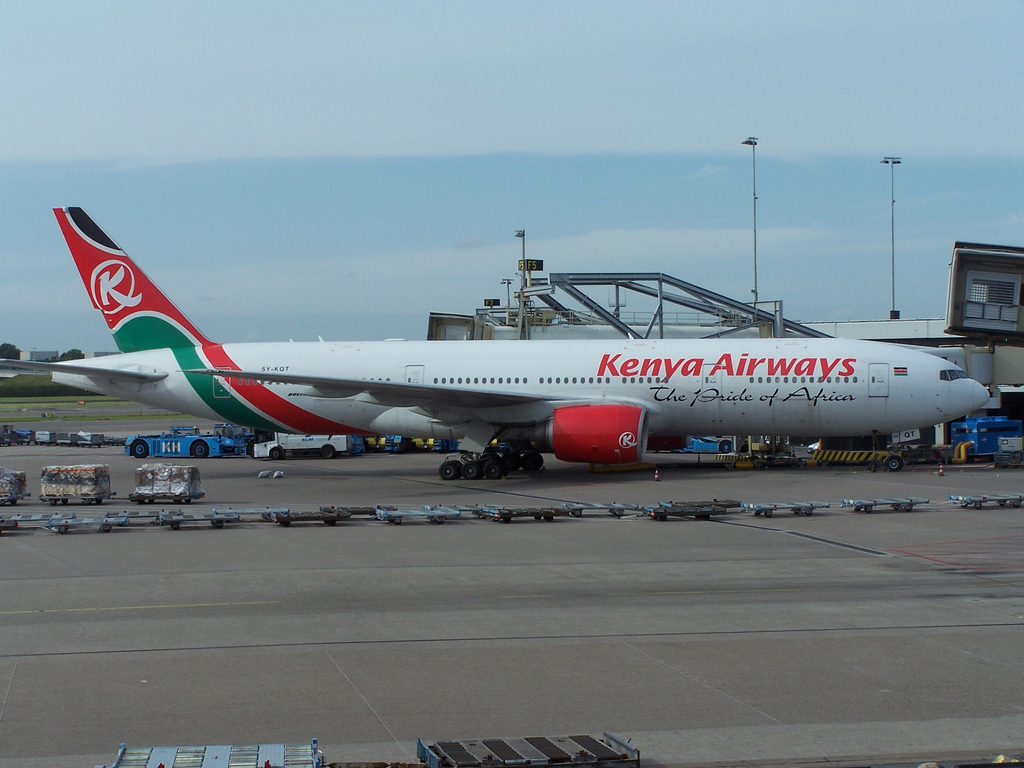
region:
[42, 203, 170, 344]
tail of the plane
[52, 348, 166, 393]
wing on the plane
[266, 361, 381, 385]
wing on the plane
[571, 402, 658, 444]
engine on the plane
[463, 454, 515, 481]
wheel of the plane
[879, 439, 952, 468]
wheel on the plane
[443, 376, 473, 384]
window on the plane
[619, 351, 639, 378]
red letter on plane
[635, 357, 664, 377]
red letter on plane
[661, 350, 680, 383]
red letter on plane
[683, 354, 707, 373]
red letter on plane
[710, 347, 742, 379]
red letter on plane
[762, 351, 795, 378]
red letter on plane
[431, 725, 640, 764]
luggage trailer on tarmac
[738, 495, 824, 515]
luggage trailer on tarmac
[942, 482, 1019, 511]
luggage trailer on tarmac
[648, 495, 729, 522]
luggage trailer on tarmac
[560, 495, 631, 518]
luggage trailer on tarmac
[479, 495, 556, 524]
luggage trailer on tarmac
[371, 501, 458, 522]
luggage trailer on tarmac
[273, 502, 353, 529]
luggage trailer on tarmac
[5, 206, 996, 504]
A jet plane at the airport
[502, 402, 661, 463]
A jet engine on a plane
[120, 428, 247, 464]
A blue tractor at the airport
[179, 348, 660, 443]
A wing on a plane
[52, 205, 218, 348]
A tail on a plane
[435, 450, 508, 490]
Tires on a plane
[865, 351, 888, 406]
A door on an airplane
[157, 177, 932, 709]
this is an airport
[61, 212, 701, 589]
this is a plane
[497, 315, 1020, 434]
the text is red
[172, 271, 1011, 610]
the plane is commercial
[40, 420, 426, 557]
these are loading carts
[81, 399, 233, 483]
the loading cart is blue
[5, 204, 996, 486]
the plane is big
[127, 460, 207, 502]
the cart is full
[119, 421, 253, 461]
the vehicle is blue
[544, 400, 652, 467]
the engine is red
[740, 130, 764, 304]
the light is tall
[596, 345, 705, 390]
the word Kenya in red letters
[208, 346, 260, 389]
red stripe on the airplane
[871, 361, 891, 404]
white closed door on the airplane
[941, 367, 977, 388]
windshield on the airplane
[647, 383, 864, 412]
the pride of Africa in black lettering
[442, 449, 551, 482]
airplanes landing gear on the runway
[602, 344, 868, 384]
red logo that says Kenya-Airways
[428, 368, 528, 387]
set of small windows on plane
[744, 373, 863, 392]
set of small windows on airplane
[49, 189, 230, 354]
the airplanes tail fin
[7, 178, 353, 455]
the airplanes rear area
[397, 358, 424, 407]
the sidedoor of the airplane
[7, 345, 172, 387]
the rear wing of the airplane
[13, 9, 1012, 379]
the sky above the airplane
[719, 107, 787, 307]
a light fixture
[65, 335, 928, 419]
the the side of the airplane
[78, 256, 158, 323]
the logo area on the plane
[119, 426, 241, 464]
the vehicle near the plane